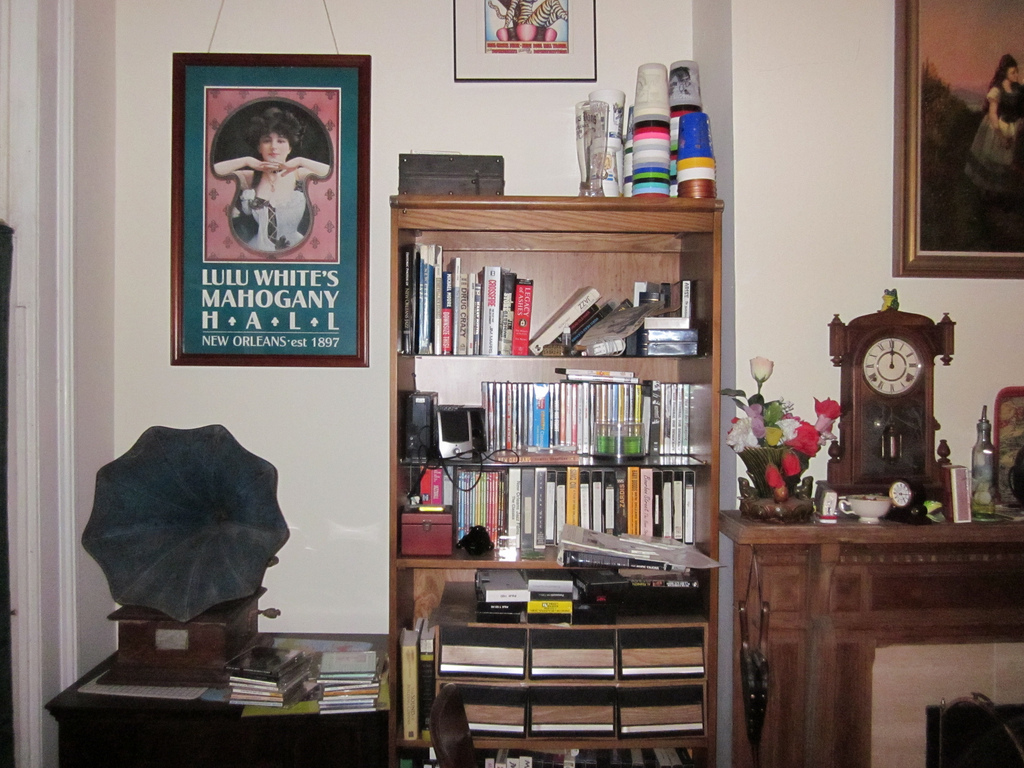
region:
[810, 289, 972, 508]
THIS IS A CLOCK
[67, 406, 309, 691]
THIS IS A GRAMOPHONE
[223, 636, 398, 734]
THESE ARE CDS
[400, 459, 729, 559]
THESE ARE VHS TAPES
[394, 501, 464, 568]
THIS IS A WOODEN BOX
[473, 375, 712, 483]
THESE ARE DVDS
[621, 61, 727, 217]
THESE ARE PLASTIC CUPS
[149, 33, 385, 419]
THIS IS A PICTURE ON THE WALL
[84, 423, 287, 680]
a vintage gramophone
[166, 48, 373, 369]
a framed theater print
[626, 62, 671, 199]
a stack of plastic cups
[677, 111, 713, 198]
a stack of plastic cups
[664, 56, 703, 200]
a stack of plastic cups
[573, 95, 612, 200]
a clear drinking glass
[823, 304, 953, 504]
a vintage clock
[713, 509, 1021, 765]
a brown wood fire place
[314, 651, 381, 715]
a stack of music CDs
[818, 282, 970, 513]
clock on the desk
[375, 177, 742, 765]
a wooden cluttered shelf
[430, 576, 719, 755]
cassette organizer on a shelf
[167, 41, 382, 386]
green and pink print on the wall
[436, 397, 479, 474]
small silver speaker on a shelf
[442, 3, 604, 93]
white print above a shelf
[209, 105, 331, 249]
woman posing on a print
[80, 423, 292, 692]
the radio is old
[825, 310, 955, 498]
the clock is old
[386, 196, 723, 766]
the books on the bookshelf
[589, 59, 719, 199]
the cups are colorful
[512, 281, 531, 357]
the book is red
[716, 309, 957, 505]
the flowers next to the clock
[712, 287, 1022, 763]
the objects on the fireplace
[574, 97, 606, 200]
the glass cup is tall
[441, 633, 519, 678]
shelf on the cabinet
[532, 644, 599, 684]
shelf on the cabinet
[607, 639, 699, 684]
shelf on the cabinet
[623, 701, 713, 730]
shelf on the cabinet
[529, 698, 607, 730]
shelf on the cabinet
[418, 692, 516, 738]
shelf on the cabinet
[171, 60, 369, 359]
picture on the wall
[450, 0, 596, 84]
picture on the wall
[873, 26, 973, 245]
picture on the wall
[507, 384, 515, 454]
book is on a shelf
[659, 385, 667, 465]
book is on a shelf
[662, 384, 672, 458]
book is on a shelf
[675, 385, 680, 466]
book is on a shelf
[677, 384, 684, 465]
book is on a shelf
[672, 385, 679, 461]
book is on a shelf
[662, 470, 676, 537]
book is on a shelf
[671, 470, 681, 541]
book is on a shelf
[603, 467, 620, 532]
book is on a shelf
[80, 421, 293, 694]
old crank-style phonograph sitting on shelf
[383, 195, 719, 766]
wooden bookcase full of miscellaneous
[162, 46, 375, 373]
antique art hanging on wall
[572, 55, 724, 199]
colorful collection of plastic cups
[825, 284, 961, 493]
wooden clock sitting on mantle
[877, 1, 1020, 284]
antique art affixed to wall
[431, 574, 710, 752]
old CD cases stacked on top of each other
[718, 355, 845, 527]
floral fixture sitting beside clock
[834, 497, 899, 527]
tea cup sitting on mantle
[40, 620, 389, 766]
end table in corner of room